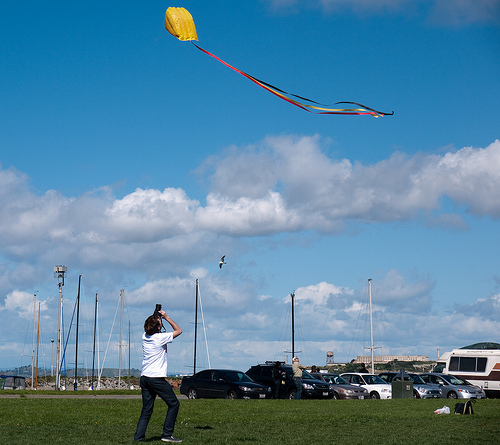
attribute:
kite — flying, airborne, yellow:
[163, 8, 199, 46]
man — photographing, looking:
[132, 307, 184, 442]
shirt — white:
[139, 329, 174, 381]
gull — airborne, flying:
[217, 253, 228, 270]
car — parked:
[178, 369, 272, 397]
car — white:
[334, 371, 392, 400]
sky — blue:
[1, 1, 499, 366]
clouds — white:
[1, 132, 500, 375]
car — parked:
[420, 371, 486, 402]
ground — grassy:
[1, 388, 498, 444]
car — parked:
[313, 371, 369, 400]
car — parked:
[381, 371, 445, 398]